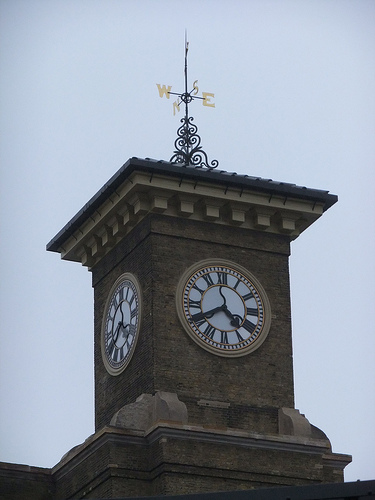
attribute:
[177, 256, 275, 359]
clock — tan, black, white, round, white faced, reading 4:40, decorative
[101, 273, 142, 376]
clock — black, white, white faced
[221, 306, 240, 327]
hour hand — black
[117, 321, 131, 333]
hour hand — black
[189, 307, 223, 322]
minute hand — black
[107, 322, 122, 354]
minute hand — black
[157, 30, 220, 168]
weather vane — ornate, metal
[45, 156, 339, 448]
clock tower — made of bricks, brown, brick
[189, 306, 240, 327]
hands — black in color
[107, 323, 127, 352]
hands — black in color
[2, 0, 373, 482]
sky — grey, blue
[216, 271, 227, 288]
number — black roman numeral, roman numeral 12, black, roman numeral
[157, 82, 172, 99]
w — gold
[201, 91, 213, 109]
e — gold